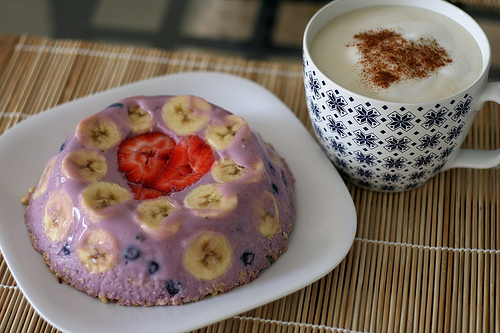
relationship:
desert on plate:
[23, 94, 300, 303] [2, 71, 360, 332]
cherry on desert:
[118, 129, 216, 200] [23, 94, 300, 303]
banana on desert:
[184, 229, 237, 280] [23, 94, 300, 303]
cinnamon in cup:
[352, 29, 453, 91] [302, 0, 499, 193]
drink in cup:
[319, 7, 484, 101] [302, 0, 499, 193]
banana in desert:
[184, 229, 237, 280] [23, 94, 300, 303]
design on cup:
[387, 107, 415, 167] [302, 0, 499, 193]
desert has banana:
[23, 94, 300, 303] [184, 229, 237, 280]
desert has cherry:
[23, 94, 300, 303] [118, 129, 216, 200]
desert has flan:
[23, 94, 300, 303] [24, 202, 290, 310]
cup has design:
[302, 0, 499, 193] [387, 107, 415, 167]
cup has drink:
[302, 0, 499, 193] [319, 7, 484, 101]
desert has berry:
[23, 94, 300, 303] [118, 129, 216, 200]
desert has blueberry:
[23, 94, 300, 303] [262, 157, 294, 200]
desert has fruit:
[23, 94, 300, 303] [85, 136, 291, 224]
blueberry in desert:
[262, 157, 294, 200] [23, 94, 300, 303]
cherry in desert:
[118, 129, 216, 200] [23, 94, 300, 303]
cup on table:
[302, 0, 499, 193] [1, 30, 497, 332]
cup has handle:
[302, 0, 499, 193] [449, 80, 500, 167]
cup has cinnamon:
[302, 0, 499, 193] [352, 29, 453, 91]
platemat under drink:
[367, 198, 499, 332] [319, 7, 484, 101]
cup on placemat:
[302, 0, 499, 193] [362, 191, 500, 330]